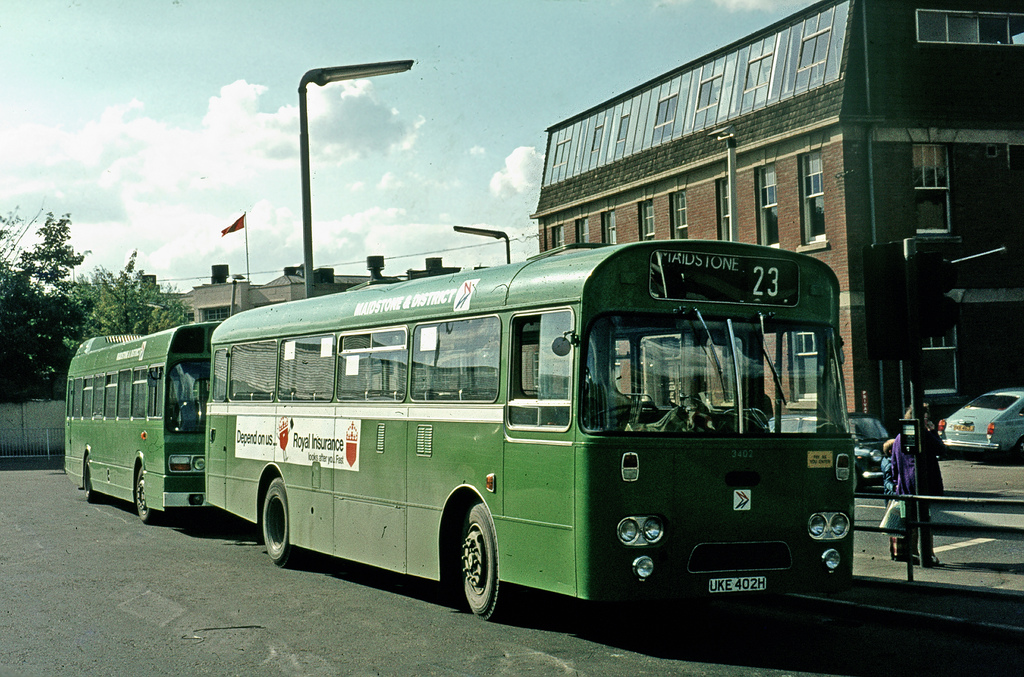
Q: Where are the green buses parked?
A: On a street.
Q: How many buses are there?
A: Two.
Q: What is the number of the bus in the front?
A: 23.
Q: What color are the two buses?
A: Green.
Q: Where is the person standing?
A: At the bus stop.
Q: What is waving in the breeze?
A: A flag.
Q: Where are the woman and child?
A: In the street.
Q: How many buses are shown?
A: Two.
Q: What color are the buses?
A: Green.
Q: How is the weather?
A: Clear.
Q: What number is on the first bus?
A: 23.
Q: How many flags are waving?
A: One.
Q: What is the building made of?
A: Brick.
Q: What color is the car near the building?
A: Light blue.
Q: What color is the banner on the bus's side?
A: White and red.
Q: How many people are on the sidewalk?
A: Two.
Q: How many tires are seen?
A: Four.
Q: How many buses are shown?
A: Two.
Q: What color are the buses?
A: Green.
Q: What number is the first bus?
A: 23.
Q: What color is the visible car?
A: White.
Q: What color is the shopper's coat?
A: Purple.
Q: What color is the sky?
A: Blue.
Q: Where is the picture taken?
A: A bus stop.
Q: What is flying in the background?
A: A flag.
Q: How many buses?
A: Two.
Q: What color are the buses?
A: Green.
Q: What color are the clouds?
A: White.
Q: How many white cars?
A: One.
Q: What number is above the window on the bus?
A: 23.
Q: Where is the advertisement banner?
A: On side of bus.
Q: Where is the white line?
A: On road.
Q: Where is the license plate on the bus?
A: Front of bus.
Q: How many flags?
A: One.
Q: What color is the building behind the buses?
A: Brown.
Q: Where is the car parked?
A: Next to the building.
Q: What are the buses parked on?
A: The pavement.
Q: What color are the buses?
A: Green.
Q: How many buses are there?
A: Two.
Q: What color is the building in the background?
A: Brown.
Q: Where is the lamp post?
A: Beside the bus.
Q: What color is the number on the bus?
A: White.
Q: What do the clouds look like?
A: Fluffy and white.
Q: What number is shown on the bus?
A: 23.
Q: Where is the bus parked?
A: At the curb.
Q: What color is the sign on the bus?
A: White.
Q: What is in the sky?
A: Clouds.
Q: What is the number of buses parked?
A: Two.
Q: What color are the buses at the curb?
A: Green.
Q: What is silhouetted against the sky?
A: Streetlight.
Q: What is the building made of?
A: Brick and glass.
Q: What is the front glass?
A: Windshield.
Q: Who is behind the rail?
A: A person.